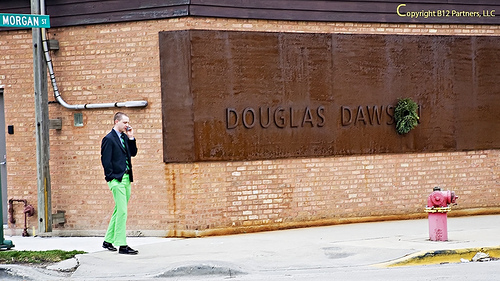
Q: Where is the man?
A: On sidewalk.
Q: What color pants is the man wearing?
A: Green.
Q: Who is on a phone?
A: The man.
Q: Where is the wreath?
A: On building.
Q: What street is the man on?
A: Morgan Street.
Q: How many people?
A: One.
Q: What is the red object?
A: Fire Hydrant.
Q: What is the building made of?
A: Brick.